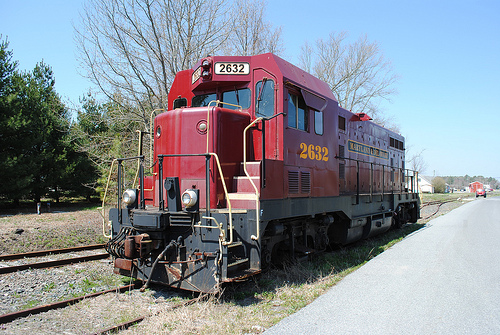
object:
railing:
[152, 151, 214, 230]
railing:
[115, 153, 146, 223]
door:
[252, 67, 280, 157]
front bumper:
[99, 198, 247, 295]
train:
[100, 52, 422, 298]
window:
[286, 87, 298, 132]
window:
[312, 109, 327, 138]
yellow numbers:
[297, 142, 310, 160]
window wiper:
[246, 76, 268, 116]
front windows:
[188, 85, 253, 110]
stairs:
[217, 157, 260, 217]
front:
[100, 57, 282, 300]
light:
[179, 191, 196, 207]